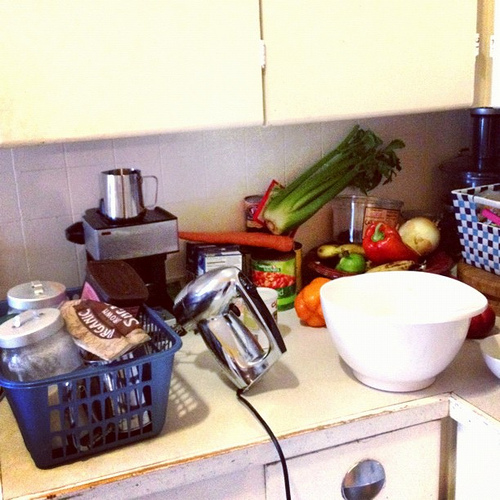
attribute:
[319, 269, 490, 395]
bowl — white, big, large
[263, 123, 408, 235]
vegetable — green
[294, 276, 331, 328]
pepper — yellow, orange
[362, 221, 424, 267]
pepper — red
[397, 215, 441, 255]
onion — white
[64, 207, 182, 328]
coffee maker — silver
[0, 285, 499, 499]
counter — white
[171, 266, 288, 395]
mixer — silver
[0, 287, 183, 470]
basket — blue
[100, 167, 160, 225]
coffee mug — silver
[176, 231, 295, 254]
carrot — large, orange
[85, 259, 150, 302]
lid — brown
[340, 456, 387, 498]
handle — silver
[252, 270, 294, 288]
tomatoes — diced